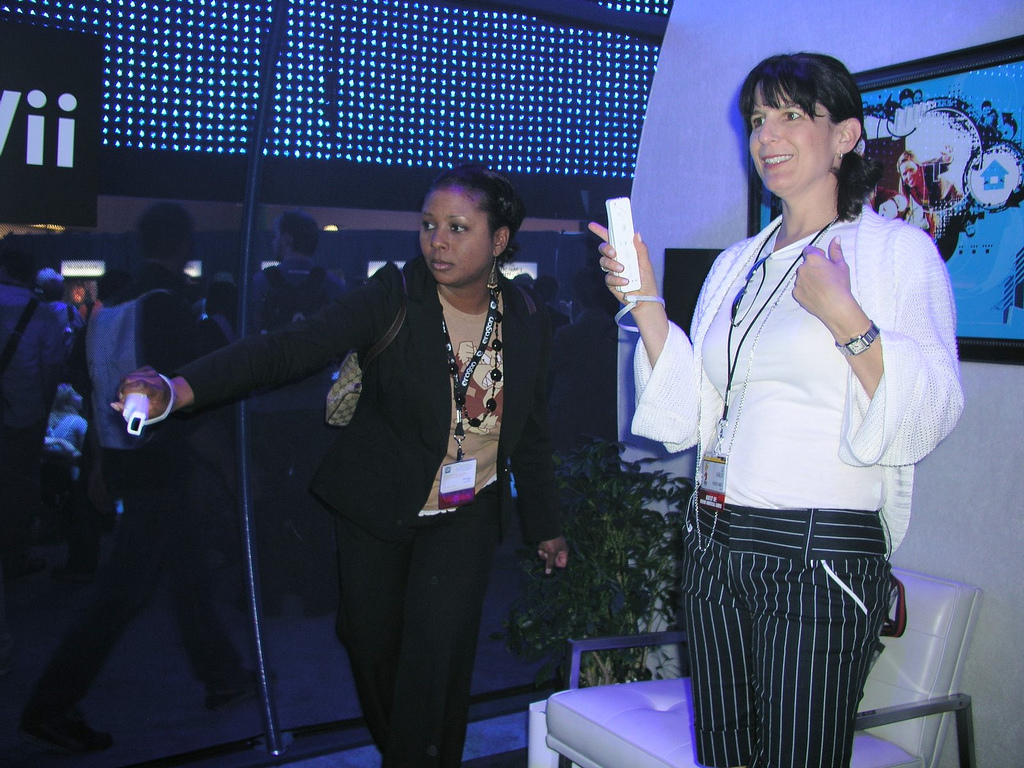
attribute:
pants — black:
[329, 489, 502, 766]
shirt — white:
[630, 207, 965, 545]